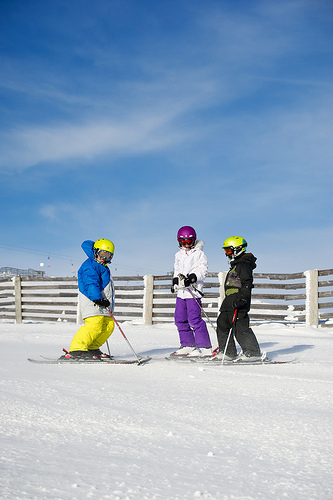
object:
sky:
[0, 0, 332, 315]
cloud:
[0, 101, 200, 172]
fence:
[0, 266, 332, 327]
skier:
[208, 236, 263, 363]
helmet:
[222, 236, 248, 259]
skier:
[170, 225, 214, 358]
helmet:
[177, 226, 197, 250]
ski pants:
[174, 296, 212, 349]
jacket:
[172, 239, 209, 300]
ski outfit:
[216, 252, 262, 359]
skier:
[64, 237, 115, 361]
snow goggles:
[93, 249, 114, 262]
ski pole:
[105, 306, 142, 364]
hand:
[94, 299, 110, 308]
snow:
[0, 320, 333, 500]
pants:
[68, 314, 115, 353]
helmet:
[93, 238, 115, 267]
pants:
[215, 310, 261, 358]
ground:
[1, 322, 333, 498]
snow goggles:
[224, 247, 241, 257]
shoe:
[87, 348, 115, 359]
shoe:
[187, 347, 214, 358]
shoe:
[232, 354, 263, 363]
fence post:
[304, 268, 320, 327]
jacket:
[76, 239, 116, 320]